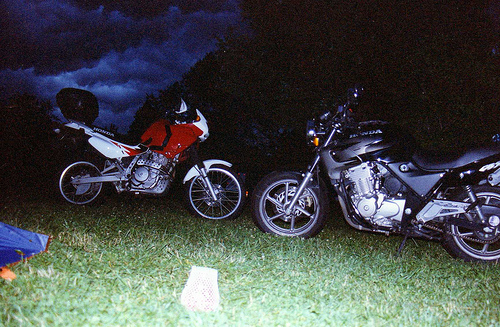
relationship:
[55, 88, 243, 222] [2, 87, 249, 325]
red honda motorcycle parked on the grass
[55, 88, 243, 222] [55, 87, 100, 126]
red motorcycle has a carrier mounted on the seat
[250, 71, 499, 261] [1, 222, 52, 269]
motorcycle rideres are on a camping trip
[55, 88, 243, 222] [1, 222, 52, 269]
motorcycle rider are pitching a tent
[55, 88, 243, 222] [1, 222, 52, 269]
motorcycle rider are on a camping trip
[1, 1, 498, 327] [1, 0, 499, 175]
camp site in mountains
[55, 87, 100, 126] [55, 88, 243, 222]
carrier on red motorcycle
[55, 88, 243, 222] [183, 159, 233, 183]
red motorcycles front tire has a white fender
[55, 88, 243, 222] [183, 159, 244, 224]
red motorcycle fender above front wheel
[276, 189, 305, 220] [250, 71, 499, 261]
disk brake of street bike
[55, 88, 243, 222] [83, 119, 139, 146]
red motorcycles has a straight seat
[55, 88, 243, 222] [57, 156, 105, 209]
red motorcycle has a high clearance on the rear wheel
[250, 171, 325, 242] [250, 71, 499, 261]
front wheel of honda street bike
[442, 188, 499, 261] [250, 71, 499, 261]
rear wheel on honda street bike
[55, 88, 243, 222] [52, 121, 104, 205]
red motorcycle rear frame has a high clearance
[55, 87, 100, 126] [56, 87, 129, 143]
carrier compartment mounted in the seat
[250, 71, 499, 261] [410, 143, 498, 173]
black motorcycle has a black seat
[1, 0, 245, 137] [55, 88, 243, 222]
white clouds behind motorcycles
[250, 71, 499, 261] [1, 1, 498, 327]
motorcycles are parked at a campsite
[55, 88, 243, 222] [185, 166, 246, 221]
red motorcycle has front wheel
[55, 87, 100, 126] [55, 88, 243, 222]
storage carrier mounted on red motorcycle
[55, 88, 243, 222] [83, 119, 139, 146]
red motorcycle can carry passengers on the seat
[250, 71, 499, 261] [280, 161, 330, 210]
black honda's front wheel has black fender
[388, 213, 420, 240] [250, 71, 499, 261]
pedal on motorcycle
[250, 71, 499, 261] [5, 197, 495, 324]
motorcycle on grass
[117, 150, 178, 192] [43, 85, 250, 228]
engine of motorcycle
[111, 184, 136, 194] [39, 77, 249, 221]
pedal of motorcycle